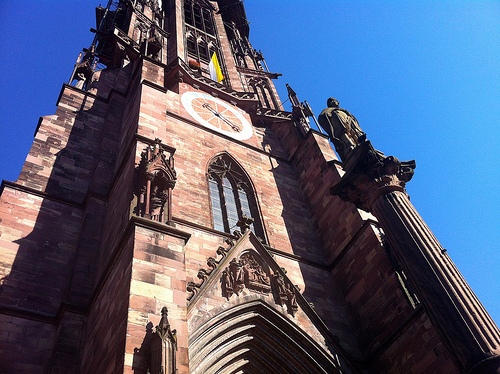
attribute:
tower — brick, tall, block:
[10, 2, 498, 367]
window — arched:
[198, 147, 267, 244]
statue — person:
[314, 93, 379, 166]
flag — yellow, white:
[204, 49, 228, 85]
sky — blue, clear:
[3, 5, 499, 336]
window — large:
[178, 3, 229, 90]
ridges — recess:
[392, 207, 405, 218]